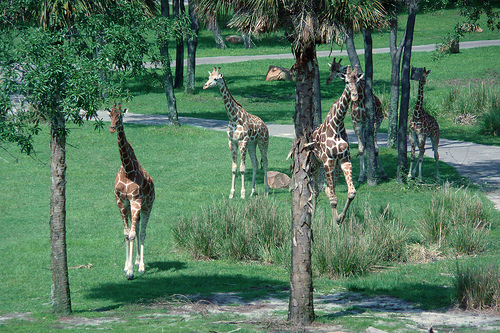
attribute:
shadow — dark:
[61, 257, 489, 317]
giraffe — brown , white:
[282, 63, 367, 227]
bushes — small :
[172, 176, 497, 274]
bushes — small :
[173, 173, 496, 318]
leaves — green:
[38, 37, 135, 90]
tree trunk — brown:
[285, 66, 318, 323]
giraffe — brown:
[85, 96, 202, 296]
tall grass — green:
[320, 182, 498, 281]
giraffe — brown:
[50, 62, 178, 302]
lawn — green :
[134, 124, 194, 191]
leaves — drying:
[192, 2, 397, 48]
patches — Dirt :
[219, 278, 498, 331]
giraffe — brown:
[106, 101, 155, 277]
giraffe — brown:
[200, 67, 271, 199]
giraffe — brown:
[310, 63, 366, 223]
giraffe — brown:
[406, 67, 441, 183]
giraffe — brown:
[324, 56, 383, 186]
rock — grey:
[265, 62, 294, 83]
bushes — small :
[447, 195, 500, 245]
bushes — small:
[376, 190, 446, 251]